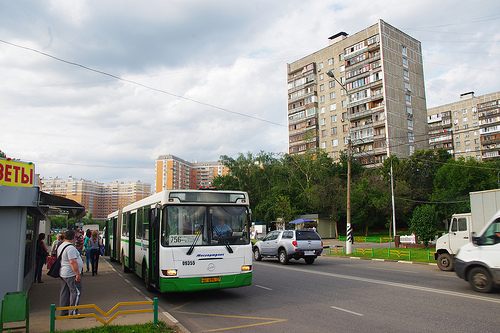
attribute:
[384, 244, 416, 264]
fence — green, yellow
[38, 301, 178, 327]
fence — green, yellow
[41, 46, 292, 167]
line — power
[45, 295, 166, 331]
fence — green, yellow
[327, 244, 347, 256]
fence section — yellow, green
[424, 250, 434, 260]
fence — green, yellow